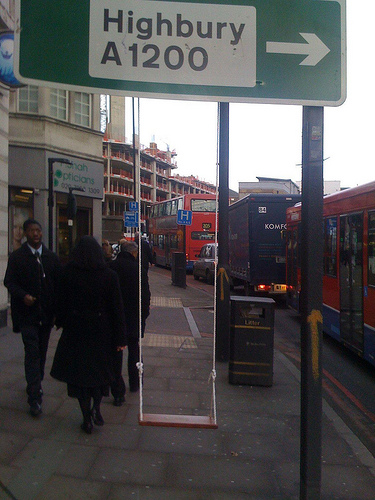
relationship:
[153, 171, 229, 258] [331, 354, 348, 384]
buses on road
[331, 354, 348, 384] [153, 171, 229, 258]
road with buses